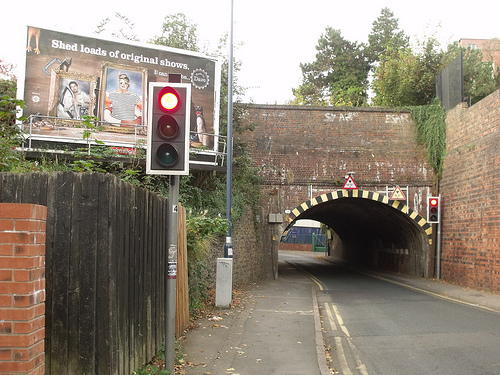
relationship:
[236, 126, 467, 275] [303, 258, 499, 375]
tunnel over street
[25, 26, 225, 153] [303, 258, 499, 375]
billboard off street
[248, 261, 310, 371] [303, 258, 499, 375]
sidewalk along street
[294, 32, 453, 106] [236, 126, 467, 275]
trees on top of tunnel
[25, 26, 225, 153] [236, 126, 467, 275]
billboard next to tunnel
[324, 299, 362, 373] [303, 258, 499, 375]
lines on street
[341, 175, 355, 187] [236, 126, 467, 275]
yield sign over tunnel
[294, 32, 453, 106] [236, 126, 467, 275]
trees on tunnel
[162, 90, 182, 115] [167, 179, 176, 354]
light on pole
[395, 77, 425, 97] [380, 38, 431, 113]
leaves on tree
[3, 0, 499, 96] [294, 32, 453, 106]
sky above trees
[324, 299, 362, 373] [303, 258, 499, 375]
lines on road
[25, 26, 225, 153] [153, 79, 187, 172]
billboard behind street signal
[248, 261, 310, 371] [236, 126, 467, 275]
sidewalk leading into tunnel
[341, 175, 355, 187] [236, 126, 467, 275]
sign over tunnel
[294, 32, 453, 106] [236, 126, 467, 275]
trees over tunnel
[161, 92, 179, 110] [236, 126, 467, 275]
light under tunnel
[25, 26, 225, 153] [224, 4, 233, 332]
billboard next to pole